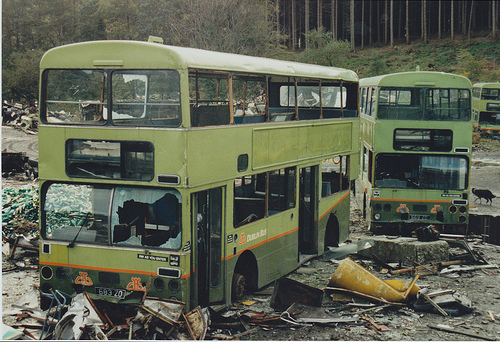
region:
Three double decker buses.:
[35, 33, 495, 325]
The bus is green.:
[25, 36, 357, 305]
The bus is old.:
[27, 39, 354, 300]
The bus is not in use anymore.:
[26, 37, 357, 314]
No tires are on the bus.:
[223, 237, 278, 302]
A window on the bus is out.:
[110, 177, 191, 267]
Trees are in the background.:
[257, 2, 487, 51]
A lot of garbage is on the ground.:
[4, 95, 498, 335]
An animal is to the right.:
[459, 174, 498, 213]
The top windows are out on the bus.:
[175, 65, 366, 132]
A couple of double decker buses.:
[23, 36, 470, 307]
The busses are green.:
[25, 34, 355, 315]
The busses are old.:
[20, 36, 357, 304]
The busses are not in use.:
[23, 30, 358, 298]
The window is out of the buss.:
[103, 184, 190, 264]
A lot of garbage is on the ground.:
[43, 263, 379, 338]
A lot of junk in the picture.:
[6, 27, 496, 336]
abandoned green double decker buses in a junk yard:
[2, 1, 498, 339]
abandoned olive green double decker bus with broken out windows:
[33, 36, 363, 318]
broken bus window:
[105, 181, 182, 251]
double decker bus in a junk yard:
[33, 23, 365, 319]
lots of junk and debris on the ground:
[321, 222, 498, 332]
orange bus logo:
[123, 268, 145, 293]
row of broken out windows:
[180, 66, 360, 128]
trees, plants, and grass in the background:
[5, 2, 498, 91]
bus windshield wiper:
[63, 207, 94, 249]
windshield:
[42, 182, 179, 249]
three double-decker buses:
[21, 13, 493, 339]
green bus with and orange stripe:
[28, 24, 357, 314]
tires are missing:
[218, 242, 280, 313]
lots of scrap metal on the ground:
[271, 254, 486, 329]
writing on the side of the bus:
[229, 226, 291, 258]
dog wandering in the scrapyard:
[463, 178, 499, 209]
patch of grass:
[331, 39, 499, 81]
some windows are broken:
[165, 46, 375, 134]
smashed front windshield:
[33, 170, 196, 273]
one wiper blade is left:
[51, 195, 96, 267]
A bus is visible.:
[371, 119, 483, 281]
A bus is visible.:
[401, 134, 498, 241]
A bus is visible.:
[371, 97, 447, 217]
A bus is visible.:
[386, 153, 431, 223]